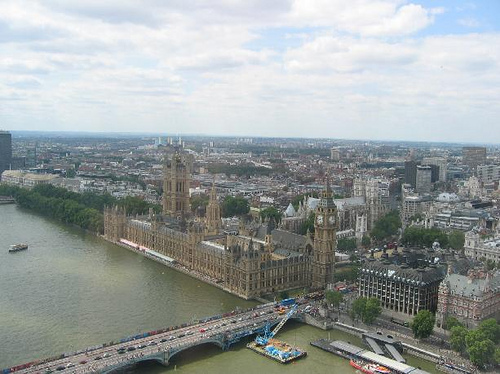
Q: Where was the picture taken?
A: London.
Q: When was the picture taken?
A: Daytime.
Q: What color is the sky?
A: Blue.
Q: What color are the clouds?
A: White.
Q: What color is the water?
A: Green.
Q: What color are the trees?
A: Green.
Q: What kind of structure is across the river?
A: A bridge.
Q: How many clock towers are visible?
A: One.